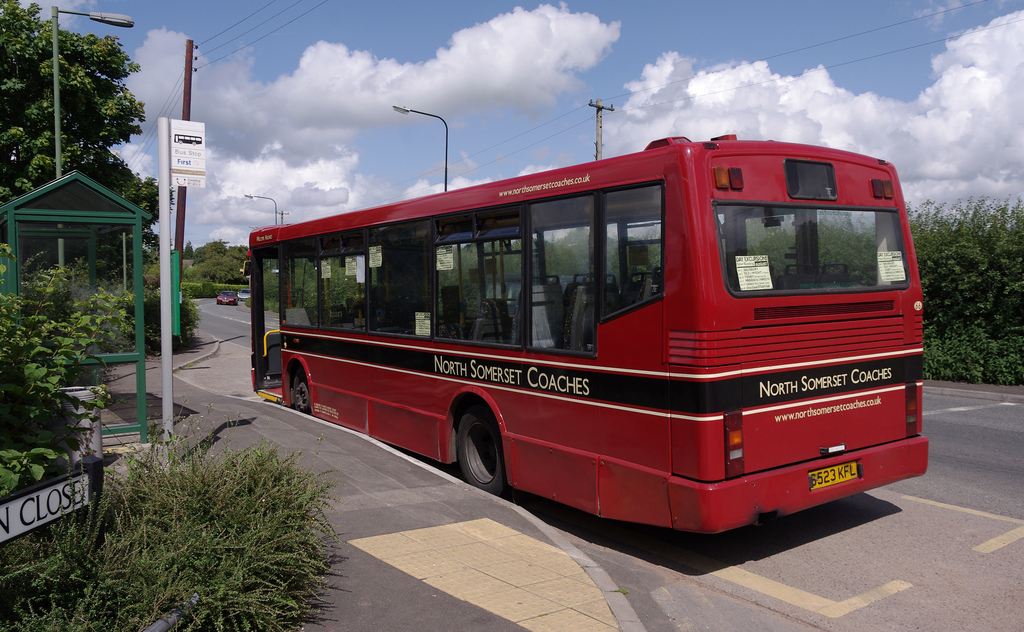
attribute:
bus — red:
[246, 137, 932, 556]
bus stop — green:
[0, 165, 150, 444]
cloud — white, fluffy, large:
[137, 1, 627, 147]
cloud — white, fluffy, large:
[141, 138, 370, 225]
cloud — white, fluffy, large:
[606, 14, 1021, 212]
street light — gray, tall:
[390, 100, 458, 181]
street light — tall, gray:
[47, 5, 134, 167]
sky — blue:
[2, 1, 1022, 256]